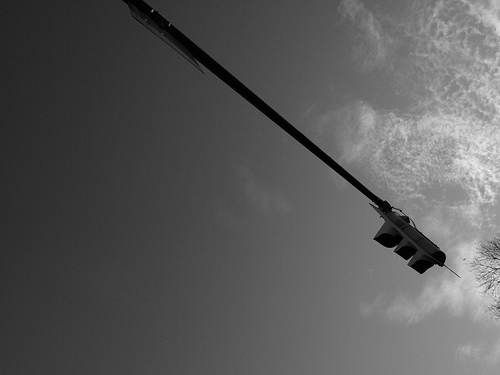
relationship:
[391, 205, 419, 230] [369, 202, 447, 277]
wire on traffic signal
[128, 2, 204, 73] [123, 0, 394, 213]
street sign attached to pole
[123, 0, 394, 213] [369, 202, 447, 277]
pole holding traffic signal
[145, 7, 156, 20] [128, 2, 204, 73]
bracket holds street sign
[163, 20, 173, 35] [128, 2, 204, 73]
bracket holds street sign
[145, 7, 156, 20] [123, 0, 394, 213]
bracket on pole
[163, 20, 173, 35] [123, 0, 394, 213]
bracket on pole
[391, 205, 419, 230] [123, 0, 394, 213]
wire on pole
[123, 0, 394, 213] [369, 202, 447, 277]
pole for traffic signal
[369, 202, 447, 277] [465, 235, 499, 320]
traffic signal near tree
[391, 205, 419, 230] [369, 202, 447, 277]
wire behind traffic signal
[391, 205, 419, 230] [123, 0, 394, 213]
wire connected to pole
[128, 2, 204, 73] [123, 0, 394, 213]
street sign on pole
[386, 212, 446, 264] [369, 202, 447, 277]
bump on traffic signal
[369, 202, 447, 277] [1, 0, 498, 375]
traffic signal in sky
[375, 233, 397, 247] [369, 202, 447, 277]
light on traffic signal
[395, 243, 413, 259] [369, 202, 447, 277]
light on traffic signal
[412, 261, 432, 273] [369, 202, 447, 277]
light on traffic signal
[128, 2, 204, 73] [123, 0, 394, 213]
street sign affixed to pole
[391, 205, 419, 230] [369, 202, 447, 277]
wire around traffic signal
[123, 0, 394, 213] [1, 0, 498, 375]
pole silhouetted against sky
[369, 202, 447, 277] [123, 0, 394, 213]
traffic signal mounted on pole